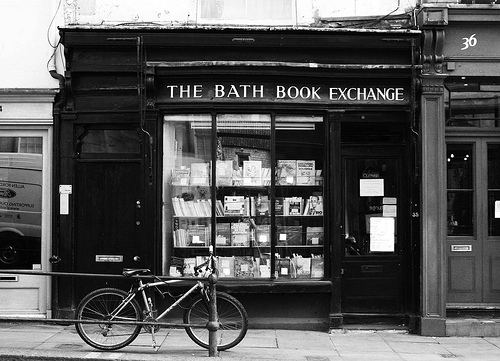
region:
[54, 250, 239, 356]
the bike is parked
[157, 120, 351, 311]
books in the shelf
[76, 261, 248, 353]
silver bike leaned against metal railing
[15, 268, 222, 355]
metal railing on edge of sidewalk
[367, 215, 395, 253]
white sign on glass of black door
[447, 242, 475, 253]
metal mail door on side of store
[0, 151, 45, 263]
white van reflection in window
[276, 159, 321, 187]
row of books on shelf inside store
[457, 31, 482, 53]
silver address numbers on top of building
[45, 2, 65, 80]
black electric lines going in to pipe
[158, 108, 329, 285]
three pane window of book store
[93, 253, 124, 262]
metal mail slot on black book store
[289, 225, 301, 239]
part of a window w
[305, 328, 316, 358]
edge of a road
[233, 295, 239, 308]
part of a bike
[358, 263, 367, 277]
part of a door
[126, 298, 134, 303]
edge of a wheel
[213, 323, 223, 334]
part of a pole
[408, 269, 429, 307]
edge of a door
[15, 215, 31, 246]
part of a window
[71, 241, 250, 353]
The bicycle has been parked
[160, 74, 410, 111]
The words "THE BATH BOOK EXCHANGE" on a sign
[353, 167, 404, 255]
White papers on the door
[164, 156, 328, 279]
Many books are on display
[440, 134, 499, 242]
Two windows on a door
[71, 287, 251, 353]
Two wheels of a bicycle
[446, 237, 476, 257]
A mailbox slot on door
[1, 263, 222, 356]
A railing made of metal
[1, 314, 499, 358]
Bicycle on a sidewalk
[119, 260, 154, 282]
Black leather bicycle seat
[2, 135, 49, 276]
reflection of van in store window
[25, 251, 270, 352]
bicycle chained to metal railing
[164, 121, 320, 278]
books displayed in window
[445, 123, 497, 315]
door with metal mail slot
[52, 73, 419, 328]
book shop with large window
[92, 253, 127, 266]
metal mail slot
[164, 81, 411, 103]
name of shop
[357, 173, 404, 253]
paper notices in shop door window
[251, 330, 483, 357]
pale gray sidewalk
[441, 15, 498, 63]
address number on top of building